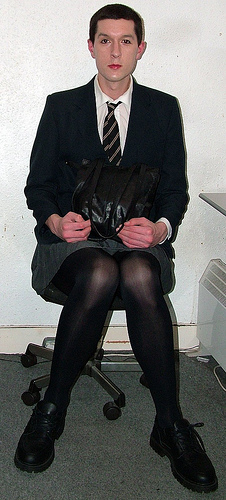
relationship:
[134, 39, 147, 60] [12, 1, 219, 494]
ear of a person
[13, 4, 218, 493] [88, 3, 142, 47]
girl has hair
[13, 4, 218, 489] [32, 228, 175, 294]
girl wearing dress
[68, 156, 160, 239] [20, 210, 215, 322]
purse on a lap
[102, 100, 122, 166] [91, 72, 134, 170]
tie and a shirt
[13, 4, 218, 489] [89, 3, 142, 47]
girl with a hair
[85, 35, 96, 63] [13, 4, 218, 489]
ear on girl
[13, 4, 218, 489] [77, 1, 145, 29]
girl has hair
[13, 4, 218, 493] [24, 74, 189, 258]
girl has jacket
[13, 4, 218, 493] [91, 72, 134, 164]
girl has shirt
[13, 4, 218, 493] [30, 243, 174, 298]
girl has dress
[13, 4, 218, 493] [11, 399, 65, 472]
girl has shoe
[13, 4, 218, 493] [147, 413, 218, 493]
girl has shoe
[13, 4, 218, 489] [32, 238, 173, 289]
girl wearing dress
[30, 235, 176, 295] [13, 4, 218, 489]
dress on girl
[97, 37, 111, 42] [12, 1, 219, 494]
eye of person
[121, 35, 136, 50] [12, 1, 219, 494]
eye of person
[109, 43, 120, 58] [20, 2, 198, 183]
nose of person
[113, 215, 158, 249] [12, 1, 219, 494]
hand of person